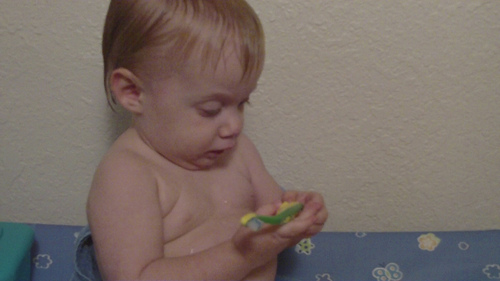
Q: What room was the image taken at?
A: It was taken at the bathroom.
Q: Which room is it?
A: It is a bathroom.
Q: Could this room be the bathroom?
A: Yes, it is the bathroom.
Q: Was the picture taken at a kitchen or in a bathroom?
A: It was taken at a bathroom.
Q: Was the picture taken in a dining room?
A: No, the picture was taken in a bathroom.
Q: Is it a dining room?
A: No, it is a bathroom.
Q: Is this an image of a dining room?
A: No, the picture is showing a bathroom.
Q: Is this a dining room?
A: No, it is a bathroom.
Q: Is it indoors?
A: Yes, it is indoors.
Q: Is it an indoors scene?
A: Yes, it is indoors.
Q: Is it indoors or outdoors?
A: It is indoors.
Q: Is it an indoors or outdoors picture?
A: It is indoors.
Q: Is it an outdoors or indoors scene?
A: It is indoors.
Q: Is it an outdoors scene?
A: No, it is indoors.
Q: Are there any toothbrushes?
A: Yes, there is a toothbrush.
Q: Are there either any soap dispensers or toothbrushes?
A: Yes, there is a toothbrush.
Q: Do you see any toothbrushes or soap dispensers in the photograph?
A: Yes, there is a toothbrush.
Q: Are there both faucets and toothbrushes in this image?
A: No, there is a toothbrush but no faucets.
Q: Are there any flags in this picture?
A: No, there are no flags.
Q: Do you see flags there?
A: No, there are no flags.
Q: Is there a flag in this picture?
A: No, there are no flags.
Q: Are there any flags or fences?
A: No, there are no flags or fences.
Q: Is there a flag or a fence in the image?
A: No, there are no flags or fences.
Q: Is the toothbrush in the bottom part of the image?
A: Yes, the toothbrush is in the bottom of the image.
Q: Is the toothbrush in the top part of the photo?
A: No, the toothbrush is in the bottom of the image.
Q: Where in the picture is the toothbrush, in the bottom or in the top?
A: The toothbrush is in the bottom of the image.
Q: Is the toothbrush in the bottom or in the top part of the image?
A: The toothbrush is in the bottom of the image.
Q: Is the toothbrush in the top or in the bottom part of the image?
A: The toothbrush is in the bottom of the image.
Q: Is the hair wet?
A: Yes, the hair is wet.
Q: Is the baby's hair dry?
A: No, the hair is wet.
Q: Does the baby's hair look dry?
A: No, the hair is wet.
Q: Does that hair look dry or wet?
A: The hair is wet.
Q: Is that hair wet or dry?
A: The hair is wet.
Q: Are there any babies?
A: Yes, there is a baby.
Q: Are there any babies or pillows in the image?
A: Yes, there is a baby.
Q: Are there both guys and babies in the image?
A: No, there is a baby but no guys.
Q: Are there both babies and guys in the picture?
A: No, there is a baby but no guys.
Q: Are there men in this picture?
A: No, there are no men.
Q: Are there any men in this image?
A: No, there are no men.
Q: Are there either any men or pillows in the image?
A: No, there are no men or pillows.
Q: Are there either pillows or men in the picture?
A: No, there are no men or pillows.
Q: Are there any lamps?
A: No, there are no lamps.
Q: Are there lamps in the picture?
A: No, there are no lamps.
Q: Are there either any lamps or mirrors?
A: No, there are no lamps or mirrors.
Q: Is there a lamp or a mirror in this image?
A: No, there are no lamps or mirrors.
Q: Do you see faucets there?
A: No, there are no faucets.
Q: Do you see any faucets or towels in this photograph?
A: No, there are no faucets or towels.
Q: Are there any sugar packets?
A: No, there are no sugar packets.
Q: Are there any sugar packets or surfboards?
A: No, there are no sugar packets or surfboards.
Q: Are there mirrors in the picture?
A: No, there are no mirrors.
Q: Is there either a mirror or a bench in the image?
A: No, there are no mirrors or benches.